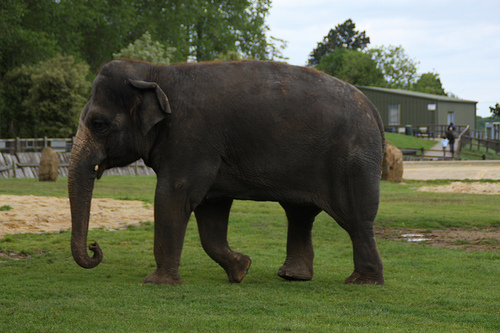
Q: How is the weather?
A: It is clear.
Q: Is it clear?
A: Yes, it is clear.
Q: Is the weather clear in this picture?
A: Yes, it is clear.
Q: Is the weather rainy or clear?
A: It is clear.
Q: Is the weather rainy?
A: No, it is clear.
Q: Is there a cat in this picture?
A: No, there are no cats.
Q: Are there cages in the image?
A: No, there are no cages.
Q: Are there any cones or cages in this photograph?
A: No, there are no cages or cones.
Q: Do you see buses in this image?
A: No, there are no buses.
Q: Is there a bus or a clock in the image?
A: No, there are no buses or clocks.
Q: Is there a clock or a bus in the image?
A: No, there are no buses or clocks.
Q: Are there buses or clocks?
A: No, there are no buses or clocks.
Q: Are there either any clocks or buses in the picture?
A: No, there are no buses or clocks.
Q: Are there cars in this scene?
A: No, there are no cars.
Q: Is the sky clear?
A: Yes, the sky is clear.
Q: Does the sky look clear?
A: Yes, the sky is clear.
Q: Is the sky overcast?
A: No, the sky is clear.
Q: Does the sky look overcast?
A: No, the sky is clear.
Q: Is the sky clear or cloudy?
A: The sky is clear.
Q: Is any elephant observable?
A: Yes, there is an elephant.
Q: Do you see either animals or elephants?
A: Yes, there is an elephant.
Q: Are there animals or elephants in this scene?
A: Yes, there is an elephant.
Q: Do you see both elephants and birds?
A: No, there is an elephant but no birds.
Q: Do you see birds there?
A: No, there are no birds.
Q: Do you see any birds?
A: No, there are no birds.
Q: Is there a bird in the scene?
A: No, there are no birds.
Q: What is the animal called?
A: The animal is an elephant.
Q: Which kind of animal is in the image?
A: The animal is an elephant.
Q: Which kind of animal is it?
A: The animal is an elephant.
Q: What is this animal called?
A: This is an elephant.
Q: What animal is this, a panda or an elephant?
A: This is an elephant.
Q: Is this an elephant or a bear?
A: This is an elephant.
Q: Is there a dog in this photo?
A: No, there are no dogs.